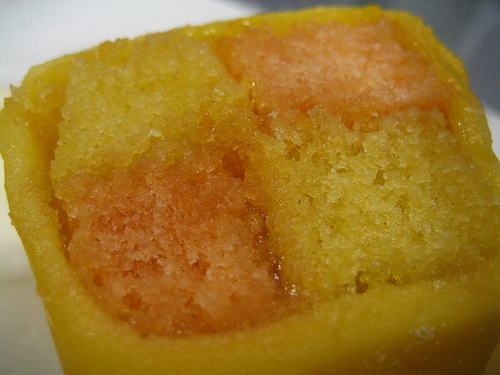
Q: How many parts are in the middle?
A: Four.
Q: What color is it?
A: Pink and yellow.